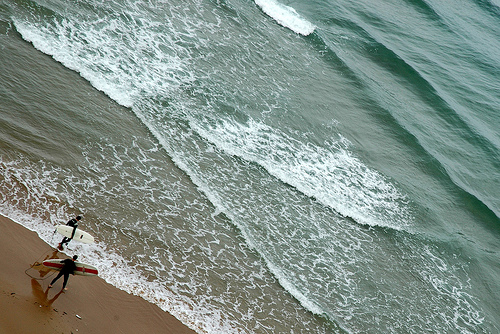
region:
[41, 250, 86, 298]
this is a person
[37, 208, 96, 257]
this is a person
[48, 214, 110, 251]
this is a surf board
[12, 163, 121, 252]
this is a wave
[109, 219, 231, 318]
this is a wave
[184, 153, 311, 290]
this is a wave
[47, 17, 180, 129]
this is a wave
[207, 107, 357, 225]
Water of the sea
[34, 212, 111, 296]
People at the beach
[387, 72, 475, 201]
Strong tides on the sea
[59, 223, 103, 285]
Surfboards in the photo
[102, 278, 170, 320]
Sand at the beach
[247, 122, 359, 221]
Water flowing on the beach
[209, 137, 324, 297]
Water covering the sand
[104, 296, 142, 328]
the sand is brown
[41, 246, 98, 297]
a person standing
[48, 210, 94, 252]
person carrying a surboard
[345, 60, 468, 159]
the water is green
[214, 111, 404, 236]
the ocean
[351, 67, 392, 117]
small waves in the water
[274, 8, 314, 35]
the white water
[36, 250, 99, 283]
person carrying a surfboard that is white and red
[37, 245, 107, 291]
this is a man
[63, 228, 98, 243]
this is a surfboard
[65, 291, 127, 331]
this is the beach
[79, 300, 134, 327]
the beach is brown in color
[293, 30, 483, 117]
this is a water body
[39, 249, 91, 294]
the man is carrying a surfboard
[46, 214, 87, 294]
the men are two in number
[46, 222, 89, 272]
the surfboard are two in number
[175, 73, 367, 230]
Water of the ocean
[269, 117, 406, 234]
Water close to the coastline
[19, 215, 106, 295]
Two people with surfboards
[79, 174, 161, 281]
Water covering the beach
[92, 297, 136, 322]
Sand at the beach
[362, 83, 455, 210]
Turbulent waters of the sea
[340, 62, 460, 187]
Waves of the sea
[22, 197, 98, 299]
People walking at the beach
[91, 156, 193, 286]
Water covering beach sand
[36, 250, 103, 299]
person on the sand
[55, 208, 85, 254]
person in the water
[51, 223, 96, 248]
white colored surfboard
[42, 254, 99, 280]
white and red colored surfboard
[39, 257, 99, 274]
red stripe on a surfboard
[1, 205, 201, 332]
wet area of sand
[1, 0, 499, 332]
green water in the ocean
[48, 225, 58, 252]
tether on the white board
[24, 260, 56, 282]
tether on the red and white board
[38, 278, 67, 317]
man's reflection on the sand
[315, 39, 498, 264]
A ripple in the water.A ripple in the water.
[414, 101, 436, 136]
A ripple in the water.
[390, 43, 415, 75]
A ripple in the water.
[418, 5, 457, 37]
A ripple in the water.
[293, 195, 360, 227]
A ripple in the water.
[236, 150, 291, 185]
A ripple in the water.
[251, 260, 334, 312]
A ripple in the water.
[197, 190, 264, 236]
A ripple in the water.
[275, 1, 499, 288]
green clear water with few ripples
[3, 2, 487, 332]
white foam from waves hitting the sandy beach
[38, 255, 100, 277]
white surfboard with red trim